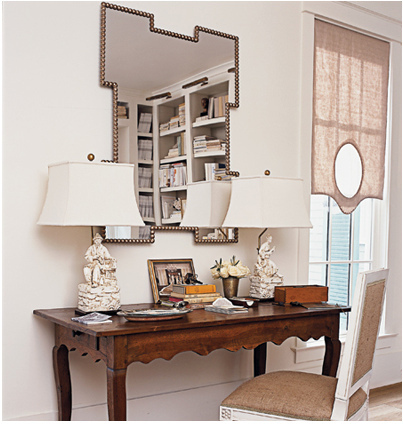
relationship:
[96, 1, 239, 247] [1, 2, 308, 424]
mirror on wall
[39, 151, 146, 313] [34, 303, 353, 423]
lamp on table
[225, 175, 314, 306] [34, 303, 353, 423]
lamp on table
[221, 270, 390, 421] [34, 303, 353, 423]
chair by desk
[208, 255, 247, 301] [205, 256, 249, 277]
vase of flowers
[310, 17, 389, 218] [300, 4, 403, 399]
curtain on door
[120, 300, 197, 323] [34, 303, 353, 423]
plate on table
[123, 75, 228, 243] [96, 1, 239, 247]
reflection in mirror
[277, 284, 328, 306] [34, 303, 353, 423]
box on table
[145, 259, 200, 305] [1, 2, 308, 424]
picture on wall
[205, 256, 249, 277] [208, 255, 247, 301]
flowers in vase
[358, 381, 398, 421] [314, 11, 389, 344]
floor under window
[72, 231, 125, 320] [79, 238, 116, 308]
sculpture at base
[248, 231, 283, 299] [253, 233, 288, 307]
sculpture at base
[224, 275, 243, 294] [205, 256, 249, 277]
bucket has roses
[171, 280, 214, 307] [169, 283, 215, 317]
stack of books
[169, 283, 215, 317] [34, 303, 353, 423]
books on desk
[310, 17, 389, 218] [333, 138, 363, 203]
shade has keyhole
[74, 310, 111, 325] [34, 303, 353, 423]
notepad on desk